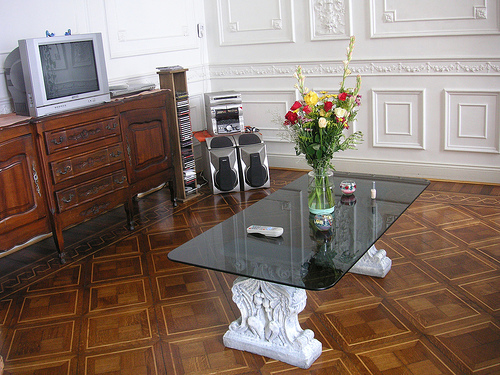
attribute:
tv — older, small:
[7, 26, 114, 136]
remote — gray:
[243, 219, 285, 239]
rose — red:
[320, 99, 333, 112]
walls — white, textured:
[195, 3, 498, 154]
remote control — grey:
[246, 223, 285, 238]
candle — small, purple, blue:
[298, 184, 360, 244]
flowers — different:
[274, 75, 351, 171]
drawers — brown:
[42, 115, 132, 215]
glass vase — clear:
[300, 161, 338, 213]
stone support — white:
[214, 287, 338, 368]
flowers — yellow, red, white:
[268, 33, 368, 175]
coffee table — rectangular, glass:
[171, 173, 426, 368]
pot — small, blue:
[310, 210, 346, 232]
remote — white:
[245, 225, 284, 236]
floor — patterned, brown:
[403, 232, 475, 327]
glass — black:
[281, 162, 426, 284]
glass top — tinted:
[163, 167, 433, 298]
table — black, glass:
[164, 163, 436, 370]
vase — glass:
[295, 157, 357, 240]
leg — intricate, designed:
[220, 237, 325, 369]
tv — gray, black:
[25, 30, 123, 108]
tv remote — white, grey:
[244, 222, 289, 237]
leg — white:
[221, 274, 325, 366]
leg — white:
[318, 201, 388, 274]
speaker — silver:
[235, 127, 271, 196]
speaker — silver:
[201, 136, 240, 199]